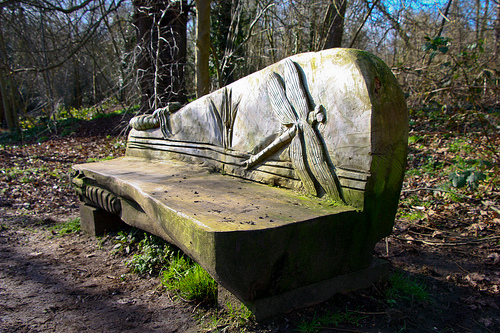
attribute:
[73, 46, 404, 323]
bench — stone, large, brown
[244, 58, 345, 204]
dragonfly — carved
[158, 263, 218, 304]
grass — patch, green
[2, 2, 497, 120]
trees — leaf-less, bare, brown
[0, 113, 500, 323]
ground — flat, bare, brown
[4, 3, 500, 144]
bush — sparse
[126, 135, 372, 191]
lines — carved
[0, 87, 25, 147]
trunk — brown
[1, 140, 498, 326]
mud — brown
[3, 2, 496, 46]
sky — blue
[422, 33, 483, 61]
leaves — green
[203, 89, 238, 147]
cattails — carved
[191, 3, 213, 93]
trunk — brown